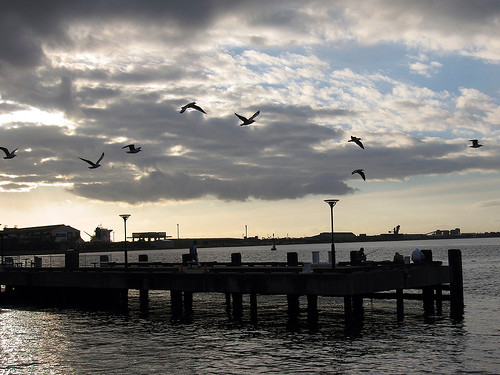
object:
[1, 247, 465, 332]
dock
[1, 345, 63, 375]
water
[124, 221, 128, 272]
post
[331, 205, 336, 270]
right post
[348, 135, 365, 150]
birds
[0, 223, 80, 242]
building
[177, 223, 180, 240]
light pole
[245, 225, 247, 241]
right light pole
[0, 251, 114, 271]
railing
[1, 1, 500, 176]
sky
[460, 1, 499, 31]
clouds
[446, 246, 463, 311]
final piling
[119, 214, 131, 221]
lamp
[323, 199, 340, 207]
right lamp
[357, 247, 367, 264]
man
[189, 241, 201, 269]
pedestrian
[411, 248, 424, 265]
person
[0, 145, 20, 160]
bird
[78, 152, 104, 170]
bird 2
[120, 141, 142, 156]
bird 3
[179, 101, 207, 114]
bird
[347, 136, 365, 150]
bird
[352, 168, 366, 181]
bird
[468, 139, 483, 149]
bird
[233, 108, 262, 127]
bird